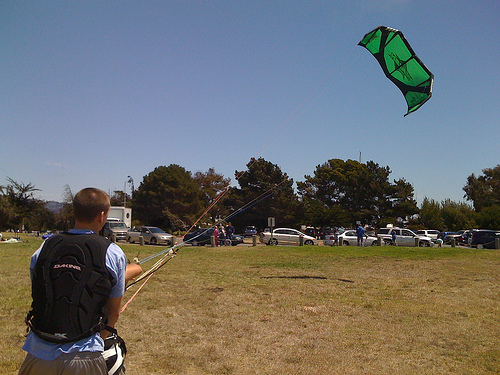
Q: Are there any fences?
A: No, there are no fences.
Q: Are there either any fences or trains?
A: No, there are no fences or trains.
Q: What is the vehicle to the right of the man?
A: The vehicle is a car.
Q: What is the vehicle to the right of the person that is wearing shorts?
A: The vehicle is a car.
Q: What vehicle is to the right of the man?
A: The vehicle is a car.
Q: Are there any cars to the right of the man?
A: Yes, there is a car to the right of the man.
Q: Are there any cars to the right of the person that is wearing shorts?
A: Yes, there is a car to the right of the man.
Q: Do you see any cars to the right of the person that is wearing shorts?
A: Yes, there is a car to the right of the man.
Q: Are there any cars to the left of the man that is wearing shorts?
A: No, the car is to the right of the man.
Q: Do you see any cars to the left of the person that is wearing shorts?
A: No, the car is to the right of the man.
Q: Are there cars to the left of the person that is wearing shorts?
A: No, the car is to the right of the man.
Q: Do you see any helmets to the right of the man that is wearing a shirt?
A: No, there is a car to the right of the man.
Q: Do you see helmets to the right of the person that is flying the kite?
A: No, there is a car to the right of the man.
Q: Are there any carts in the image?
A: No, there are no carts.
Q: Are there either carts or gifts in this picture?
A: No, there are no carts or gifts.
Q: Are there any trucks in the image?
A: Yes, there is a truck.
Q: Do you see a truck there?
A: Yes, there is a truck.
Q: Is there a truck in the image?
A: Yes, there is a truck.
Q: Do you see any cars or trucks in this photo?
A: Yes, there is a truck.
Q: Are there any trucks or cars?
A: Yes, there is a truck.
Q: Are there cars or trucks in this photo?
A: Yes, there is a truck.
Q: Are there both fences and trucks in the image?
A: No, there is a truck but no fences.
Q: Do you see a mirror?
A: No, there are no mirrors.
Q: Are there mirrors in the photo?
A: No, there are no mirrors.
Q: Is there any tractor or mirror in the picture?
A: No, there are no mirrors or tractors.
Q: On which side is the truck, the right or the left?
A: The truck is on the left of the image.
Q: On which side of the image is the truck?
A: The truck is on the left of the image.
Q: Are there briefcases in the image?
A: No, there are no briefcases.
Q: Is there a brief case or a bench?
A: No, there are no briefcases or benches.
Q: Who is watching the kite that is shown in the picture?
A: The family is watching the kite.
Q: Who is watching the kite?
A: The family is watching the kite.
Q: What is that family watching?
A: The family is watching the kite.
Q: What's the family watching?
A: The family is watching the kite.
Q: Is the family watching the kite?
A: Yes, the family is watching the kite.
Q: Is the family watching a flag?
A: No, the family is watching the kite.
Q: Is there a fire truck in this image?
A: No, there are no fire trucks.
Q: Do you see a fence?
A: No, there are no fences.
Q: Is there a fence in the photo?
A: No, there are no fences.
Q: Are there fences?
A: No, there are no fences.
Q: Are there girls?
A: No, there are no girls.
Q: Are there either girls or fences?
A: No, there are no girls or fences.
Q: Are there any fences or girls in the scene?
A: No, there are no girls or fences.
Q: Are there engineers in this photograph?
A: No, there are no engineers.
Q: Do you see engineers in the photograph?
A: No, there are no engineers.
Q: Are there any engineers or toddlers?
A: No, there are no engineers or toddlers.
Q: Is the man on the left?
A: Yes, the man is on the left of the image.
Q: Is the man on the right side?
A: No, the man is on the left of the image.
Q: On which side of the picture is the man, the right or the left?
A: The man is on the left of the image.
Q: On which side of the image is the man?
A: The man is on the left of the image.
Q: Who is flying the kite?
A: The man is flying the kite.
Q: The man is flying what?
A: The man is flying the kite.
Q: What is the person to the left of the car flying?
A: The man is flying the kite.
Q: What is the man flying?
A: The man is flying the kite.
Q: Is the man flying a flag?
A: No, the man is flying the kite.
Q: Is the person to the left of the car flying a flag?
A: No, the man is flying the kite.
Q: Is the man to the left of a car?
A: Yes, the man is to the left of a car.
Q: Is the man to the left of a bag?
A: No, the man is to the left of a car.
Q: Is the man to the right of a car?
A: No, the man is to the left of a car.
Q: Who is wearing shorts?
A: The man is wearing shorts.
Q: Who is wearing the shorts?
A: The man is wearing shorts.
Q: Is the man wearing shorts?
A: Yes, the man is wearing shorts.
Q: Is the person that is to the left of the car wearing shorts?
A: Yes, the man is wearing shorts.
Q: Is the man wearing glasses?
A: No, the man is wearing shorts.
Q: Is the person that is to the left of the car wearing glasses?
A: No, the man is wearing shorts.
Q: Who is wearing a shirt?
A: The man is wearing a shirt.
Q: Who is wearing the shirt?
A: The man is wearing a shirt.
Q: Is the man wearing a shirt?
A: Yes, the man is wearing a shirt.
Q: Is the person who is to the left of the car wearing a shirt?
A: Yes, the man is wearing a shirt.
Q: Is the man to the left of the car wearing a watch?
A: No, the man is wearing a shirt.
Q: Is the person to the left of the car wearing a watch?
A: No, the man is wearing a shirt.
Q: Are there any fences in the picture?
A: No, there are no fences.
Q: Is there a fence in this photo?
A: No, there are no fences.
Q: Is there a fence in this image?
A: No, there are no fences.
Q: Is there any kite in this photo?
A: Yes, there is a kite.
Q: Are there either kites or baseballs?
A: Yes, there is a kite.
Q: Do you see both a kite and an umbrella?
A: No, there is a kite but no umbrellas.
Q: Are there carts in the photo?
A: No, there are no carts.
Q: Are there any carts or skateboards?
A: No, there are no carts or skateboards.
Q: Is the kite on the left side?
A: No, the kite is on the right of the image.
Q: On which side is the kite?
A: The kite is on the right of the image.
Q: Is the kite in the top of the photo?
A: Yes, the kite is in the top of the image.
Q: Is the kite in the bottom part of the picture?
A: No, the kite is in the top of the image.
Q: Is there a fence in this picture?
A: No, there are no fences.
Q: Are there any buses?
A: No, there are no buses.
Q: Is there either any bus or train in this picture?
A: No, there are no buses or trains.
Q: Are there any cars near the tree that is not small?
A: Yes, there is a car near the tree.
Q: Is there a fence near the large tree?
A: No, there is a car near the tree.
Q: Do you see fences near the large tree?
A: No, there is a car near the tree.